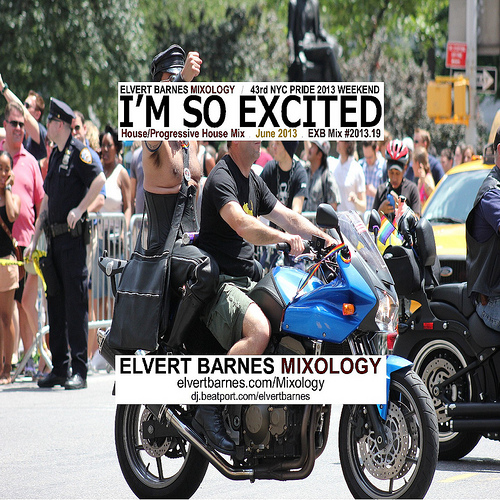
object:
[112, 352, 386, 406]
sign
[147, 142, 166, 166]
armpit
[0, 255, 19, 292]
skirt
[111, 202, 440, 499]
bike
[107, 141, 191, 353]
bag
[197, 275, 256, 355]
shorts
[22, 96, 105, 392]
officer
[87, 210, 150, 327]
fence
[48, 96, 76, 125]
hat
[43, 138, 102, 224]
shirt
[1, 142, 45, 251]
shirt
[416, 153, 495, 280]
taxi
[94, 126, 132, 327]
woman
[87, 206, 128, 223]
railing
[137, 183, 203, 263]
corset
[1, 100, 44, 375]
people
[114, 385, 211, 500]
tire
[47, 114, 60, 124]
sunglasses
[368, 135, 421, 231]
man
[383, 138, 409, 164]
helmet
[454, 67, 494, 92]
arrow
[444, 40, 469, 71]
sign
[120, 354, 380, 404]
details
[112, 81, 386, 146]
flyer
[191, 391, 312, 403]
address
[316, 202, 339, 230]
mirror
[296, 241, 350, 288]
flag